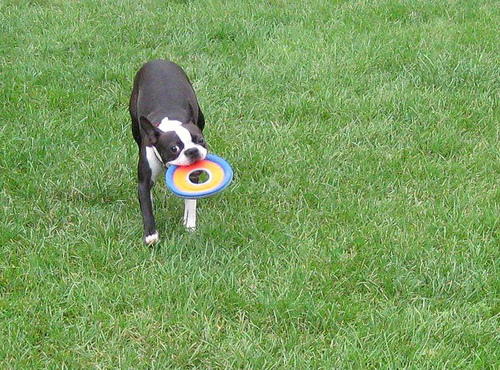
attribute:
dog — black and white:
[130, 54, 210, 247]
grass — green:
[0, 66, 497, 283]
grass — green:
[11, 114, 478, 370]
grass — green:
[14, 76, 485, 370]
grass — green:
[245, 55, 492, 347]